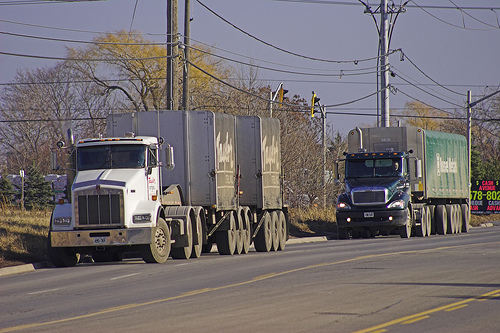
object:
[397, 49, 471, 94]
wires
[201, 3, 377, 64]
wires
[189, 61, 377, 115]
wires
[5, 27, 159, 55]
wires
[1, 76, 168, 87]
wires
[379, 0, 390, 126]
poles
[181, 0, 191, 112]
poles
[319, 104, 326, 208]
poles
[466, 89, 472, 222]
poles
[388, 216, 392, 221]
lights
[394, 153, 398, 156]
lights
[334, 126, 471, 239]
semi trailer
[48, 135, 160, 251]
front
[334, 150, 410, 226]
front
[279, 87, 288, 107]
street sign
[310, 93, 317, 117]
street sign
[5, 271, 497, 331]
roadway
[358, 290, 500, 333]
line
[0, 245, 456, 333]
line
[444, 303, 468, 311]
line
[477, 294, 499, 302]
line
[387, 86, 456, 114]
wires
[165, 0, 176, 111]
poles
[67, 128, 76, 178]
exhaust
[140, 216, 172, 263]
tire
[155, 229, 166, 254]
rim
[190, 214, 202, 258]
tires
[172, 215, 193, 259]
tire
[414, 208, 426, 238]
tire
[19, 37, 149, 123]
trees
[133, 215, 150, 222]
light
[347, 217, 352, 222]
light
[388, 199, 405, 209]
light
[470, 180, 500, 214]
bulletin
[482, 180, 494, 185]
word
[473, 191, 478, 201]
number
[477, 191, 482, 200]
number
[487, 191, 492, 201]
number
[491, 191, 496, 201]
number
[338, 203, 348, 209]
light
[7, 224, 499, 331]
street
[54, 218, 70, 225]
headlights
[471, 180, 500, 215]
sign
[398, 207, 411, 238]
tire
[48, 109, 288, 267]
semi trailer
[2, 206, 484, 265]
grass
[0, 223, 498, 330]
road